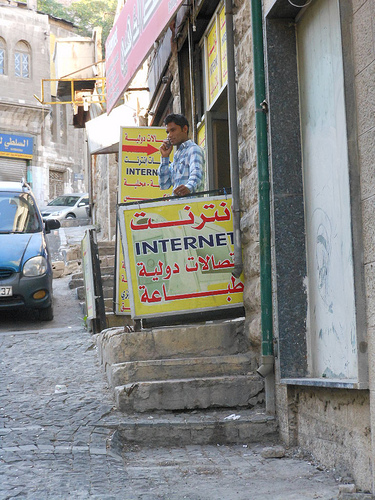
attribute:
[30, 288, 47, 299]
light — little, yellow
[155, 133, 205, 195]
shirt — plaid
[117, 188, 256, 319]
sign — tall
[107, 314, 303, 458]
stairs — concrete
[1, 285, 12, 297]
plate — partial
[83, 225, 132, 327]
stairs — uneven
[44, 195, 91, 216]
car — silver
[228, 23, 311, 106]
pipe — green, gray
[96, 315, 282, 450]
stairs — stone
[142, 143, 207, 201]
shirt — plaid